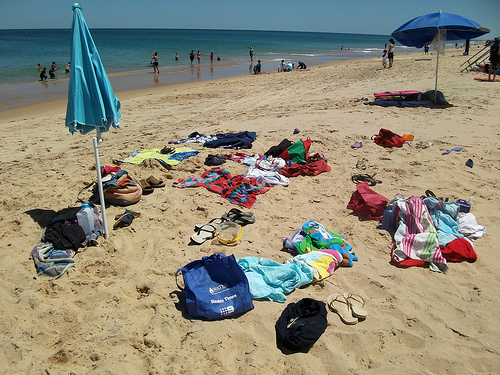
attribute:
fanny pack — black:
[272, 288, 339, 355]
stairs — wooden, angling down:
[456, 41, 493, 77]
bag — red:
[343, 180, 388, 222]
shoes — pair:
[330, 290, 365, 323]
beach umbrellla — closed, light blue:
[62, 0, 124, 244]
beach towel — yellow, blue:
[123, 145, 198, 165]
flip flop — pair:
[343, 291, 366, 321]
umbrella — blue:
[66, 0, 116, 245]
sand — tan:
[1, 40, 495, 372]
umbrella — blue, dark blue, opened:
[392, 10, 489, 94]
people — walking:
[135, 38, 260, 75]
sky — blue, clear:
[0, 0, 500, 42]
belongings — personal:
[245, 135, 330, 190]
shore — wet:
[13, 25, 325, 109]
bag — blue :
[168, 248, 262, 326]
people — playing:
[26, 41, 61, 95]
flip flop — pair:
[328, 294, 355, 323]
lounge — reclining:
[376, 89, 443, 109]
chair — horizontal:
[361, 65, 436, 122]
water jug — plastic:
[74, 199, 99, 234]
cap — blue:
[82, 201, 90, 210]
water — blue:
[0, 27, 485, 84]